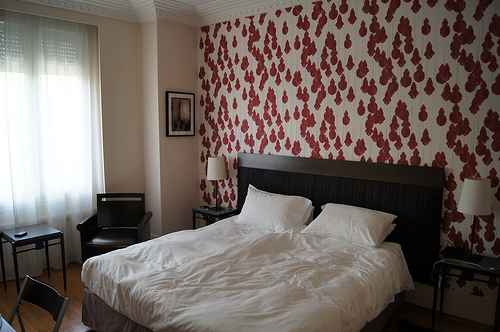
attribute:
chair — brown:
[76, 191, 151, 262]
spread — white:
[192, 219, 327, 270]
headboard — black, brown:
[235, 148, 442, 279]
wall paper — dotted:
[202, 1, 497, 253]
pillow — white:
[301, 198, 397, 248]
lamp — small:
[201, 143, 238, 218]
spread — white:
[69, 170, 433, 326]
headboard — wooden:
[234, 152, 441, 299]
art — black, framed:
[163, 89, 195, 138]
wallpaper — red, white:
[190, 2, 498, 259]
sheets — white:
[80, 215, 416, 329]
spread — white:
[186, 226, 364, 317]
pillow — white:
[256, 196, 317, 233]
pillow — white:
[232, 178, 300, 232]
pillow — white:
[325, 215, 401, 248]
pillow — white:
[308, 198, 392, 248]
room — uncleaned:
[9, 5, 488, 327]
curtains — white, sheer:
[5, 12, 105, 243]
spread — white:
[81, 219, 415, 330]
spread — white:
[82, 191, 409, 329]